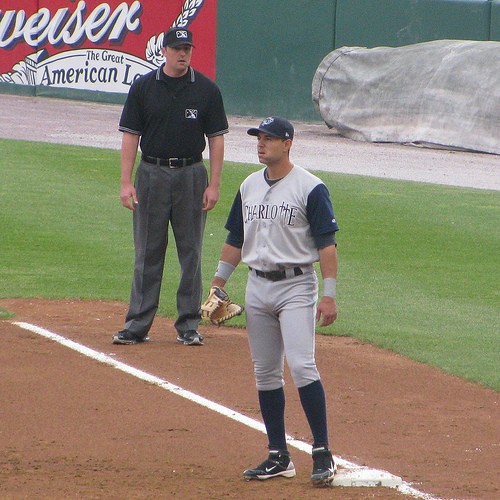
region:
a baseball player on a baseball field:
[203, 118, 340, 486]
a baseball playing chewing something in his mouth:
[252, 118, 294, 165]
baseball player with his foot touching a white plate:
[309, 443, 402, 488]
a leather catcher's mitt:
[198, 285, 243, 327]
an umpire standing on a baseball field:
[113, 26, 231, 341]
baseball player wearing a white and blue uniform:
[226, 161, 340, 450]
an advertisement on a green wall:
[0, 0, 217, 87]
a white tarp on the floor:
[311, 33, 498, 149]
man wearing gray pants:
[126, 166, 208, 346]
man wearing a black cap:
[161, 26, 195, 48]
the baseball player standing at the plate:
[202, 115, 337, 485]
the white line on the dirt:
[10, 322, 440, 499]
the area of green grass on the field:
[0, 135, 499, 390]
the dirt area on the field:
[0, 295, 495, 495]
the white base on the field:
[331, 468, 401, 485]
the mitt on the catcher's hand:
[200, 287, 242, 323]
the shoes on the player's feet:
[241, 447, 337, 487]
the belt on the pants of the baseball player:
[246, 265, 315, 280]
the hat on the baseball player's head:
[247, 116, 294, 139]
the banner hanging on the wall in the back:
[0, 0, 217, 88]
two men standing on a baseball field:
[88, 40, 372, 482]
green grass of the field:
[382, 208, 483, 339]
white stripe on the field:
[113, 354, 230, 431]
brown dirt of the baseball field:
[25, 385, 182, 482]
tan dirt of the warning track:
[21, 96, 93, 133]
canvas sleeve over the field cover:
[326, 53, 496, 133]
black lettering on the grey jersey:
[244, 201, 307, 237]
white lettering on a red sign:
[12, 0, 138, 40]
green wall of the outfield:
[240, 13, 289, 98]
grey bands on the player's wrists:
[191, 259, 343, 310]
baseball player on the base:
[197, 117, 341, 484]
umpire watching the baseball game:
[110, 27, 230, 346]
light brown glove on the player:
[195, 287, 242, 327]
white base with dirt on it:
[327, 465, 399, 489]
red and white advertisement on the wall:
[0, 0, 219, 100]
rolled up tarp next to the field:
[310, 43, 497, 155]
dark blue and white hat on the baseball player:
[245, 115, 292, 138]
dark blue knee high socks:
[253, 378, 330, 458]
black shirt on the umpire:
[117, 68, 229, 163]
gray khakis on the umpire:
[115, 154, 211, 340]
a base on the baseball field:
[300, 458, 413, 495]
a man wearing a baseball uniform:
[190, 104, 351, 493]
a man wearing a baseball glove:
[195, 106, 347, 490]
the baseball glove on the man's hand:
[190, 275, 246, 331]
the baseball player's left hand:
[313, 288, 345, 328]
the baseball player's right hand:
[195, 278, 246, 327]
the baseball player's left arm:
[302, 177, 354, 335]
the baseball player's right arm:
[190, 185, 260, 331]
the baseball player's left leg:
[275, 279, 370, 486]